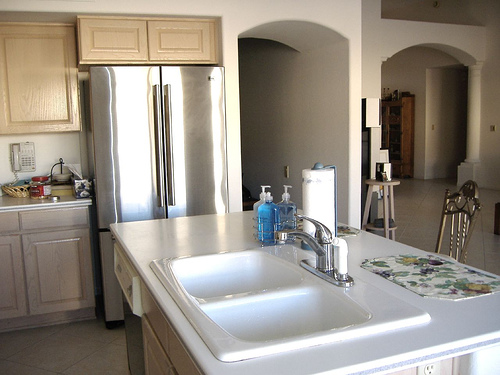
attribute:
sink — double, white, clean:
[215, 299, 331, 353]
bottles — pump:
[251, 187, 292, 238]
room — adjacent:
[360, 0, 499, 262]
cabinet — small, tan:
[77, 15, 149, 67]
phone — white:
[8, 138, 40, 177]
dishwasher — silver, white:
[110, 239, 146, 374]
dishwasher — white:
[100, 233, 157, 373]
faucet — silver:
[268, 208, 350, 276]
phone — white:
[11, 145, 36, 170]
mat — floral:
[358, 249, 498, 303]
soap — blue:
[249, 194, 297, 245]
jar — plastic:
[31, 174, 52, 199]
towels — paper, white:
[299, 168, 334, 245]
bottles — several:
[246, 187, 307, 239]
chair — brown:
[433, 179, 473, 259]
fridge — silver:
[87, 65, 238, 323]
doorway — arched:
[236, 19, 353, 214]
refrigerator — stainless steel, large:
[85, 69, 232, 222]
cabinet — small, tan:
[146, 18, 217, 62]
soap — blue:
[255, 200, 277, 241]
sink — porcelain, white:
[151, 238, 443, 358]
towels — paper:
[298, 169, 331, 243]